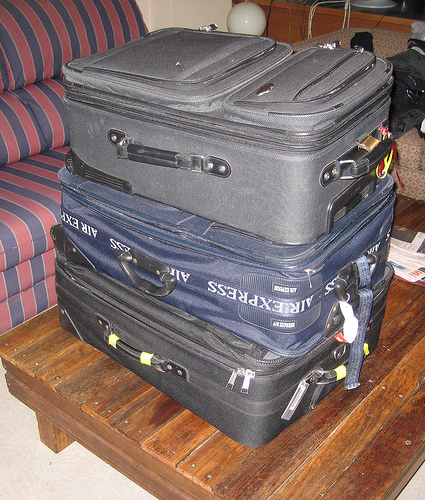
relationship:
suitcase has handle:
[27, 16, 404, 440] [118, 144, 213, 188]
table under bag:
[31, 344, 159, 487] [27, 16, 404, 440]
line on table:
[28, 315, 62, 373] [31, 344, 159, 487]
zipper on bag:
[297, 245, 351, 295] [143, 180, 405, 369]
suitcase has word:
[27, 16, 404, 440] [368, 134, 405, 186]